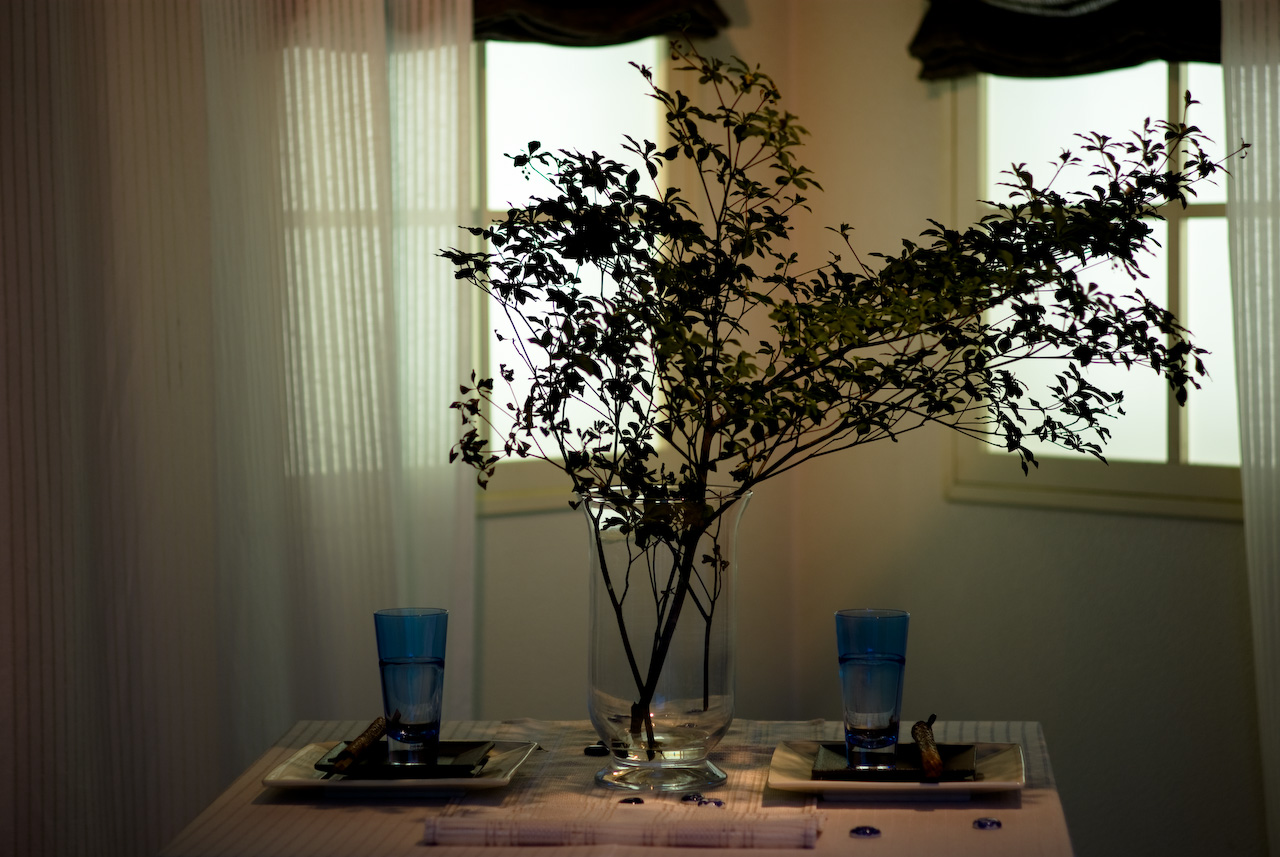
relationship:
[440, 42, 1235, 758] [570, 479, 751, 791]
branch in vase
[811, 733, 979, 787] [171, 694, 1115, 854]
plate on table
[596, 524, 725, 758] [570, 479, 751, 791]
water in vase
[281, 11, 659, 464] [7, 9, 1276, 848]
window in dining room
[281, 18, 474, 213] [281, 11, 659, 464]
pane on window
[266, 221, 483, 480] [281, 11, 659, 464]
pane on window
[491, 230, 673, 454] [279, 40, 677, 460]
pane on window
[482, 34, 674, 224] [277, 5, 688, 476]
pane on window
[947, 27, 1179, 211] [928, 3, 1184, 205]
pane on window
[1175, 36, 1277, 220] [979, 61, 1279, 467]
pane on pane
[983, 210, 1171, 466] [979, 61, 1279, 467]
pane on pane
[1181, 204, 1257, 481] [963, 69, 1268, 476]
pane on window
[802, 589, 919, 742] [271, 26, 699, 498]
pane in window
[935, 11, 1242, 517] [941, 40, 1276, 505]
pane in window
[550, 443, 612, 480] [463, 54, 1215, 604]
leaf on stem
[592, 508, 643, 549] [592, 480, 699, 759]
leaf on stem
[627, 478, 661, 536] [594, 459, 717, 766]
leaf on stem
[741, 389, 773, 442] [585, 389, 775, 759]
leaf on stem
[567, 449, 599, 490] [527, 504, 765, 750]
leaf on stem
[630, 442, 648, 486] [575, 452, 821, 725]
leaf on stem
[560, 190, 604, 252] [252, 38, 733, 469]
leaf on stem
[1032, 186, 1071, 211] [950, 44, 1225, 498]
leaf on stem